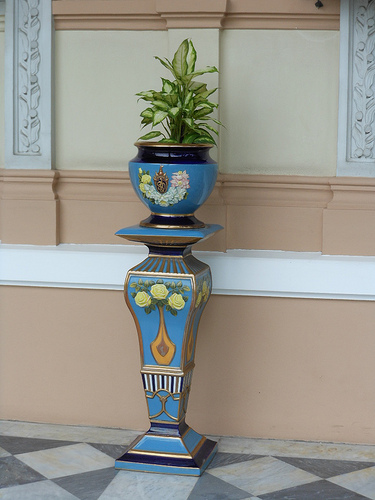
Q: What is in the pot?
A: A plant.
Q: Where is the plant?
A: In the pot.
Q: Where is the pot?
A: On the stand.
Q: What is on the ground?
A: Vase on stand.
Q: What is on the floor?
A: Vase on stand.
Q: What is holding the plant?
A: Decorated vase.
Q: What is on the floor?
A: Decorated stand.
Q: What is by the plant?
A: Gray molding.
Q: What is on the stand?
A: Plant in pot.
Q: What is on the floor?
A: Pot stand.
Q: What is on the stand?
A: Plant in pot.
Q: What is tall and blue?
A: The vase.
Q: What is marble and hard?
A: The floor.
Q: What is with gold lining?
A: A vase.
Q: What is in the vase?
A: A plant.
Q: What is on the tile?
A: Checkered pattern.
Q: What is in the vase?
A: A plant.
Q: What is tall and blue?
A: A vase.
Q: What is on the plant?
A: Leaves.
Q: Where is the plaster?
A: On wall.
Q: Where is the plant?
A: In the vase.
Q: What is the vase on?
A: Stand.